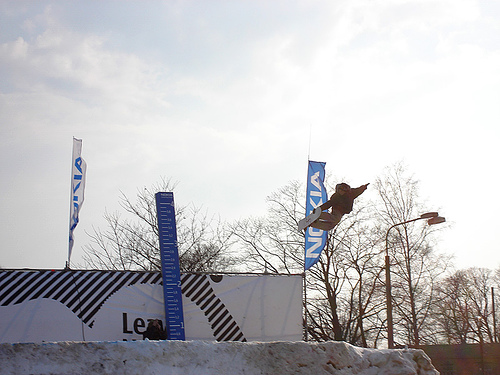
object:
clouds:
[315, 83, 325, 94]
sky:
[0, 0, 500, 349]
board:
[154, 189, 186, 341]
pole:
[384, 255, 395, 350]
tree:
[371, 153, 440, 349]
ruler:
[154, 189, 187, 340]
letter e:
[133, 317, 147, 335]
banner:
[0, 269, 304, 343]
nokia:
[69, 156, 83, 242]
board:
[297, 206, 322, 233]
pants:
[310, 207, 343, 231]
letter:
[121, 311, 134, 334]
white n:
[305, 237, 322, 259]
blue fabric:
[303, 121, 329, 272]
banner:
[63, 134, 87, 270]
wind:
[0, 0, 495, 371]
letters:
[74, 156, 83, 174]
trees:
[455, 264, 496, 344]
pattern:
[0, 267, 249, 342]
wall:
[394, 342, 500, 375]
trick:
[296, 181, 371, 233]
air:
[0, 0, 500, 375]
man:
[304, 181, 372, 232]